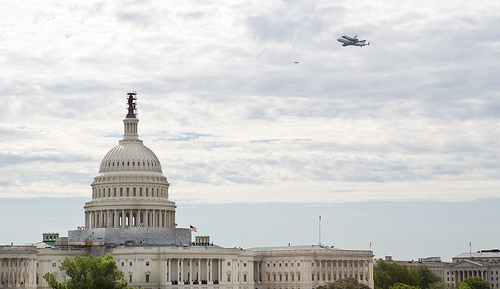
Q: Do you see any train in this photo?
A: No, there are no trains.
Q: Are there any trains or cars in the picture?
A: No, there are no trains or cars.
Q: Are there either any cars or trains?
A: No, there are no trains or cars.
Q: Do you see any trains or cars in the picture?
A: No, there are no trains or cars.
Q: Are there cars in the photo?
A: No, there are no cars.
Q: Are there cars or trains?
A: No, there are no cars or trains.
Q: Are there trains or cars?
A: No, there are no cars or trains.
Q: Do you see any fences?
A: Yes, there is a fence.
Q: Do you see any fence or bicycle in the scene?
A: Yes, there is a fence.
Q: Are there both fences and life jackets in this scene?
A: No, there is a fence but no life jackets.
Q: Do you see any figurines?
A: No, there are no figurines.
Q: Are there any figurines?
A: No, there are no figurines.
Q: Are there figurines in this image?
A: No, there are no figurines.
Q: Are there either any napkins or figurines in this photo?
A: No, there are no figurines or napkins.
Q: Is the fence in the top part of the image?
A: No, the fence is in the bottom of the image.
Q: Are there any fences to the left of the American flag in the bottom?
A: Yes, there is a fence to the left of the American flag.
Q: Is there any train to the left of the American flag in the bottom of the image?
A: No, there is a fence to the left of the American flag.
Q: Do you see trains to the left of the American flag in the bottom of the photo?
A: No, there is a fence to the left of the American flag.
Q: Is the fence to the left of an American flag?
A: Yes, the fence is to the left of an American flag.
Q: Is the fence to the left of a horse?
A: No, the fence is to the left of an American flag.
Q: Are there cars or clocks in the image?
A: No, there are no clocks or cars.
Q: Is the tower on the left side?
A: Yes, the tower is on the left of the image.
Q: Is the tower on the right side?
A: No, the tower is on the left of the image.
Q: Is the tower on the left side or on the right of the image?
A: The tower is on the left of the image.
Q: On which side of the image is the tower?
A: The tower is on the left of the image.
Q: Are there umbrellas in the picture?
A: No, there are no umbrellas.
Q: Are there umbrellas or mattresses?
A: No, there are no umbrellas or mattresses.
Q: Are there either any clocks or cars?
A: No, there are no cars or clocks.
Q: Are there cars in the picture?
A: No, there are no cars.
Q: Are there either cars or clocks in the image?
A: No, there are no cars or clocks.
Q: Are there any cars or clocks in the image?
A: No, there are no clocks or cars.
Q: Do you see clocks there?
A: No, there are no clocks.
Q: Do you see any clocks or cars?
A: No, there are no clocks or cars.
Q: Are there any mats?
A: No, there are no mats.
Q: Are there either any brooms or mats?
A: No, there are no mats or brooms.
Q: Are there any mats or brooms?
A: No, there are no mats or brooms.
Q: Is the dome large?
A: Yes, the dome is large.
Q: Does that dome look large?
A: Yes, the dome is large.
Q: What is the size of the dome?
A: The dome is large.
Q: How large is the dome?
A: The dome is large.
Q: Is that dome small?
A: No, the dome is large.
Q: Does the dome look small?
A: No, the dome is large.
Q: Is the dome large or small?
A: The dome is large.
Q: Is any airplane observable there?
A: Yes, there is an airplane.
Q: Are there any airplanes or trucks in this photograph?
A: Yes, there is an airplane.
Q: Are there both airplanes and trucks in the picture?
A: No, there is an airplane but no trucks.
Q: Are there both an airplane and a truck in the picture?
A: No, there is an airplane but no trucks.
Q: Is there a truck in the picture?
A: No, there are no trucks.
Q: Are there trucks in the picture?
A: No, there are no trucks.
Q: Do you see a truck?
A: No, there are no trucks.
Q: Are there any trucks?
A: No, there are no trucks.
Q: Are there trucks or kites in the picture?
A: No, there are no trucks or kites.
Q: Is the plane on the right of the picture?
A: Yes, the plane is on the right of the image.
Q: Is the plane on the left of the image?
A: No, the plane is on the right of the image.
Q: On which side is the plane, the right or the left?
A: The plane is on the right of the image.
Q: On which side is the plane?
A: The plane is on the right of the image.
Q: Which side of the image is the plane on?
A: The plane is on the right of the image.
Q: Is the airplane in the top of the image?
A: Yes, the airplane is in the top of the image.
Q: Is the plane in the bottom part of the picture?
A: No, the plane is in the top of the image.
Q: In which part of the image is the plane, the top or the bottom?
A: The plane is in the top of the image.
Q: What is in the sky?
A: The plane is in the sky.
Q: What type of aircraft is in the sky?
A: The aircraft is an airplane.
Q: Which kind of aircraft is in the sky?
A: The aircraft is an airplane.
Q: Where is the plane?
A: The plane is in the sky.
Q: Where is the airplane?
A: The plane is in the sky.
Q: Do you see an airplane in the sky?
A: Yes, there is an airplane in the sky.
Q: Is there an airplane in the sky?
A: Yes, there is an airplane in the sky.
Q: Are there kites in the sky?
A: No, there is an airplane in the sky.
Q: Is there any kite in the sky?
A: No, there is an airplane in the sky.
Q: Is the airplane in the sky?
A: Yes, the airplane is in the sky.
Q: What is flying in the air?
A: The plane is flying in the air.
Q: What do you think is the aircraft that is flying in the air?
A: The aircraft is an airplane.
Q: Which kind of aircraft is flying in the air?
A: The aircraft is an airplane.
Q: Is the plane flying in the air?
A: Yes, the plane is flying in the air.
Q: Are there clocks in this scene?
A: No, there are no clocks.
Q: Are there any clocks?
A: No, there are no clocks.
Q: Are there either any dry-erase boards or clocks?
A: No, there are no clocks or dry-erase boards.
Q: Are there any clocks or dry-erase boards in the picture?
A: No, there are no clocks or dry-erase boards.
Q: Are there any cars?
A: No, there are no cars.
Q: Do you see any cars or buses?
A: No, there are no cars or buses.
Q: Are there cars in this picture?
A: No, there are no cars.